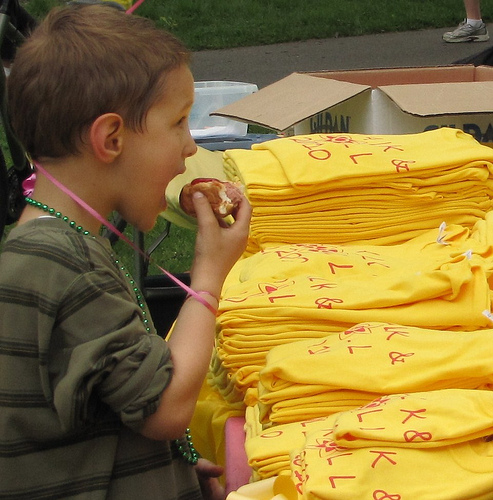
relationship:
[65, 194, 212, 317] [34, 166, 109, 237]
ribbon around neck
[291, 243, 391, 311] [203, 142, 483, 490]
writing on shirts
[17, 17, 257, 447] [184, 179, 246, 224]
boy eating hotdog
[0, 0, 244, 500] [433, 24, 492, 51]
boy wearing sneakers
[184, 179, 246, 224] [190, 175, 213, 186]
hotdog has ketchup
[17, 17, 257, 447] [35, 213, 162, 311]
boy wearing beads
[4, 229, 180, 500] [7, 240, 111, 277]
shirt has stripes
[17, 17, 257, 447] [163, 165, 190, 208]
boy has mouth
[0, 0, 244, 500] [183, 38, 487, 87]
boy on sidewalk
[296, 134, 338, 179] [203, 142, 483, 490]
letters on shirts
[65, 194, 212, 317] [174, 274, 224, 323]
ribbon around wrist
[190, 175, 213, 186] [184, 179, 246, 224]
ketchup on hotdog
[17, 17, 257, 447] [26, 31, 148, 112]
boy has hair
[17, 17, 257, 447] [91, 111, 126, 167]
boy has ear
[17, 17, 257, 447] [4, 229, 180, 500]
boy wearing shirt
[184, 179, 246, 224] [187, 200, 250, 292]
hotdog in hand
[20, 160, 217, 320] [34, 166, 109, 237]
ribbon around neck